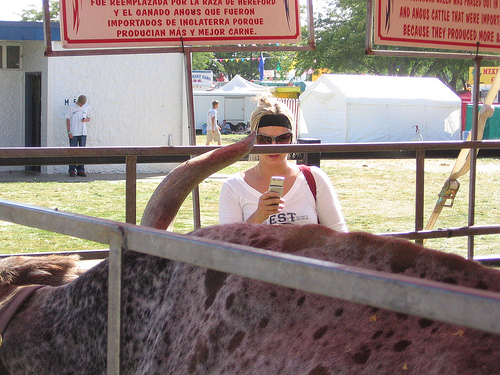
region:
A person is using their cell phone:
[123, 76, 401, 271]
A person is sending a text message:
[156, 81, 422, 266]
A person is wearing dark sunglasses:
[137, 83, 452, 279]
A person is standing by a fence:
[155, 80, 475, 331]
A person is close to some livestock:
[30, 81, 480, 331]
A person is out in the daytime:
[20, 80, 470, 345]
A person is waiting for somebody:
[100, 80, 475, 331]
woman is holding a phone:
[205, 93, 325, 245]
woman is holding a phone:
[230, 105, 329, 265]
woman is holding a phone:
[212, 92, 323, 272]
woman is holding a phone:
[202, 93, 327, 273]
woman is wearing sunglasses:
[245, 124, 304, 159]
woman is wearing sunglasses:
[237, 107, 319, 178]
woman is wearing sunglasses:
[230, 122, 310, 155]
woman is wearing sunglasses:
[242, 114, 317, 170]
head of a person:
[239, 96, 301, 180]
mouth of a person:
[253, 136, 315, 177]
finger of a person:
[243, 192, 295, 219]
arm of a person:
[313, 155, 358, 249]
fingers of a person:
[262, 189, 294, 211]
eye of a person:
[256, 119, 280, 161]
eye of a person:
[279, 132, 294, 149]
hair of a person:
[257, 103, 289, 117]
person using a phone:
[233, 146, 308, 234]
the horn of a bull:
[140, 129, 262, 242]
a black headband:
[254, 111, 295, 128]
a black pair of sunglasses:
[253, 132, 293, 143]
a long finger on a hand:
[257, 190, 277, 202]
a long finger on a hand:
[262, 197, 287, 205]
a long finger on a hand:
[265, 204, 286, 209]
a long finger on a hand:
[264, 208, 284, 215]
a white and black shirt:
[220, 165, 344, 230]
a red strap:
[298, 161, 320, 191]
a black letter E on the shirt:
[265, 211, 277, 223]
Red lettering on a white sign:
[103, 25, 169, 40]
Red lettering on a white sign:
[165, 26, 190, 40]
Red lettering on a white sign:
[197, 26, 235, 44]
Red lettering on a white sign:
[225, 26, 262, 43]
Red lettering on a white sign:
[99, 15, 165, 30]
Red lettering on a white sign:
[163, 15, 236, 32]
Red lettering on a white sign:
[228, 13, 272, 28]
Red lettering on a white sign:
[398, 23, 486, 50]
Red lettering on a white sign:
[396, 4, 496, 33]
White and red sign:
[86, 1, 301, 43]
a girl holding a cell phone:
[215, 87, 349, 240]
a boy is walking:
[201, 95, 224, 151]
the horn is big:
[135, 127, 262, 256]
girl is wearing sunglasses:
[252, 131, 295, 148]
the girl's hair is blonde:
[247, 94, 296, 139]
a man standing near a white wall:
[63, 94, 93, 180]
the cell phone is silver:
[264, 175, 286, 202]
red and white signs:
[55, 0, 497, 55]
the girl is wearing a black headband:
[253, 114, 295, 131]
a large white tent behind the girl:
[292, 72, 463, 152]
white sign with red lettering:
[57, 0, 303, 44]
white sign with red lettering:
[371, 0, 498, 55]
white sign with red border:
[57, 0, 302, 52]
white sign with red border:
[371, 0, 498, 47]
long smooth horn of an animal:
[128, 124, 255, 233]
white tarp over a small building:
[295, 71, 464, 148]